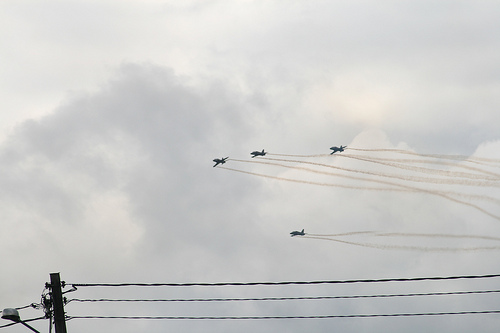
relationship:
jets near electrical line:
[213, 144, 350, 238] [7, 267, 499, 332]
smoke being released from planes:
[322, 153, 497, 260] [196, 118, 364, 254]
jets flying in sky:
[213, 144, 350, 238] [1, 1, 498, 331]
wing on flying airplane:
[212, 161, 217, 169] [210, 155, 228, 167]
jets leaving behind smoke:
[198, 114, 353, 182] [273, 160, 461, 270]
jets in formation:
[213, 144, 350, 238] [204, 122, 365, 240]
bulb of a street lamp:
[3, 305, 20, 323] [2, 300, 32, 330]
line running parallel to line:
[60, 307, 497, 320] [60, 272, 499, 289]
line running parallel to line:
[60, 272, 499, 289] [60, 287, 497, 306]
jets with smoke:
[213, 144, 350, 238] [341, 145, 496, 198]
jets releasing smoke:
[213, 144, 350, 238] [306, 225, 498, 254]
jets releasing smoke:
[213, 144, 350, 238] [218, 160, 498, 200]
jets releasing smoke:
[213, 144, 350, 238] [263, 150, 498, 218]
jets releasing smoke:
[213, 144, 350, 238] [344, 143, 498, 186]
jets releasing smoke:
[213, 144, 350, 238] [302, 232, 498, 253]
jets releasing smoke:
[213, 144, 350, 238] [217, 156, 498, 218]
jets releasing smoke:
[213, 144, 350, 238] [263, 151, 498, 199]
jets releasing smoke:
[213, 144, 350, 238] [341, 147, 498, 174]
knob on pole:
[38, 279, 54, 294] [49, 273, 69, 331]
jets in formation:
[213, 144, 350, 238] [203, 142, 345, 247]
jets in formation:
[213, 144, 350, 238] [212, 139, 345, 239]